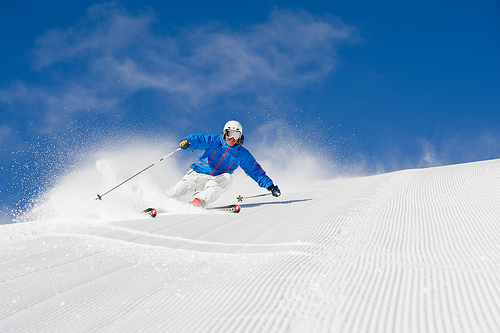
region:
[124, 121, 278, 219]
skier in snow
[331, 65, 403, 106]
white clouds in blue sky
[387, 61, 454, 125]
white clouds in blue sky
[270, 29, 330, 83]
white clouds in blue sky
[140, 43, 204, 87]
white clouds in blue sky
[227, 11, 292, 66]
white clouds in blue sky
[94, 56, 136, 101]
white clouds in blue sky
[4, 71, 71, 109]
white clouds in blue sky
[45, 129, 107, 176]
white clouds in blue sky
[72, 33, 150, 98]
white clouds in blue sky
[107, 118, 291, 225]
skier on hill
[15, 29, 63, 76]
white clouds in blue sky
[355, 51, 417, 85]
white clouds in blue sky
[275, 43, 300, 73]
white clouds in blue sky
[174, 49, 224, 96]
white clouds in blue sky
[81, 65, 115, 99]
white clouds in blue sky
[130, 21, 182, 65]
white clouds in blue sky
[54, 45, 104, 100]
white clouds in blue sky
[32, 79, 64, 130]
white clouds in blue sky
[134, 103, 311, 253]
skier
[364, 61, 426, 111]
white clouds in blue sky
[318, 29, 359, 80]
white clouds in blue sky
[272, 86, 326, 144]
white clouds in blue sky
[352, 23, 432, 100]
white clouds in blue sky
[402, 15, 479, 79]
white clouds in blue sky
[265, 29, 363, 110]
white clouds in blue sky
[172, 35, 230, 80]
white clouds in blue sky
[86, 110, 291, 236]
A person in the foreground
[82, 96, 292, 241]
Person in the foreground is skiing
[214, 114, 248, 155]
Person is wearing a helmet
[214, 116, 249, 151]
The helmet is white in color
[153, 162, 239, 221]
Person is wearing white pants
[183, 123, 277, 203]
Person is wearing a blue coat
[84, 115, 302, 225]
Person is skiing down a hill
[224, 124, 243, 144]
Person is wearing reflective goggles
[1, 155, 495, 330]
Snow is covering the ground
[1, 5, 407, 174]
Light clouds are in the sky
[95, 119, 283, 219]
skier coming down a hill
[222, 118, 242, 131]
helmet of a skier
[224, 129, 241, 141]
reflective ski goggles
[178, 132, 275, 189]
light blue ski parka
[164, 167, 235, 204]
white ski pants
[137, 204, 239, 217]
red and black downhill skis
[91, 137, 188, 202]
ski pole in skier's right hand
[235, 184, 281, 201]
ski pole in skier's left hand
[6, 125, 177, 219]
snow behind a skier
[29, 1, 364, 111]
thin clouds in a blue sky